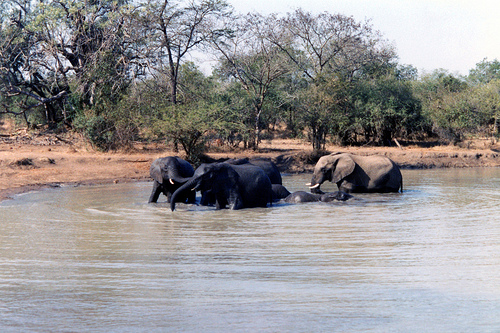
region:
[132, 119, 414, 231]
group of gray elephants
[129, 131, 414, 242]
elephants in the water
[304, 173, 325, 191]
two sharp white tusks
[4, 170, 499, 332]
shallow body of water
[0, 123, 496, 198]
ground covered in brown dirt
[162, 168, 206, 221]
trunk sticking in the water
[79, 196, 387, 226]
small ripples in the water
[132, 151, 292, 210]
elephants playing together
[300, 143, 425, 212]
elephant standing in the water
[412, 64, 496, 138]
green tree tops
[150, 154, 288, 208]
Two black elephants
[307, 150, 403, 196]
One grey elephant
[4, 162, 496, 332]
A small shallow pond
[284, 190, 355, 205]
A small elephant cub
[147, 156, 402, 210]
Three adult elephants only have feet in water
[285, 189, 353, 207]
Elephant cub almost completely immersed in water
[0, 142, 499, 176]
Land without green grass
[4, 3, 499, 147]
Many green trees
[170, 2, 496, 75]
Blue sky without clouds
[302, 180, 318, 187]
Two white elephant tusks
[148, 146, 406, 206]
elephants bathing in the water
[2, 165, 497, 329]
large body of water for elephants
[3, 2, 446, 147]
trees in the distance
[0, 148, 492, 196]
shore area next to the water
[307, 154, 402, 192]
top portion of an elephant in water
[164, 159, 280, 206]
the elephant's trunk is extended out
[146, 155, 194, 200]
the elephant's trunk is swinging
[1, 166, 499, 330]
pool of water where elephants bathe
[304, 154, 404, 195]
elephant is walking in the water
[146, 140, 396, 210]
herd of elephants swimming in the water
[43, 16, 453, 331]
a group of elephants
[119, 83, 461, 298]
a group of elephants in the water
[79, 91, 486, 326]
a group of elephants in water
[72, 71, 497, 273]
an elephant in a body of water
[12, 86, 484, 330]
a body of water with elephants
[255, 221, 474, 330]
a body of water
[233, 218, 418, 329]
a calm body of water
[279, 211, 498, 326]
a body of water that is calm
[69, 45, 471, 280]
elephants together in water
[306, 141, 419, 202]
This is an elephant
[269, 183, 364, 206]
This is an elephant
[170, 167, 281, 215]
This is an elephant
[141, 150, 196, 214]
This is an elephant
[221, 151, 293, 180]
This is an elephant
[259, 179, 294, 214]
This is an elephant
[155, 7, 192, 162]
This is a tree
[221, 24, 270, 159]
This is a tree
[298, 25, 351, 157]
This is a tree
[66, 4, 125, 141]
This is a tree